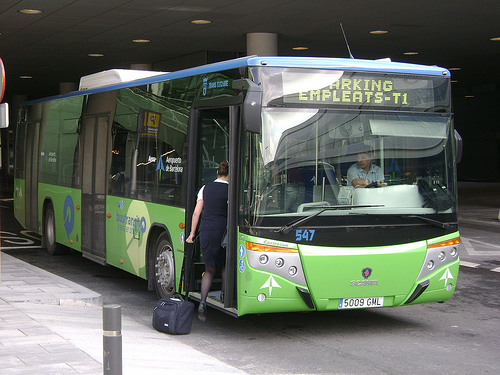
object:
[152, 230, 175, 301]
wheel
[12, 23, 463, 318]
bus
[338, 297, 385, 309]
license plate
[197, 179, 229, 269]
black dress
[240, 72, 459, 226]
window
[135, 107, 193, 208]
window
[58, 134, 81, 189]
window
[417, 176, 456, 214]
backpack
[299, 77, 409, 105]
lcd screen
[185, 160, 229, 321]
woman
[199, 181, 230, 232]
vest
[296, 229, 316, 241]
number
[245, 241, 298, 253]
turn signal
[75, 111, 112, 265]
doors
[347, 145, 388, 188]
driver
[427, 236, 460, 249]
signal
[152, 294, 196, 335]
bag